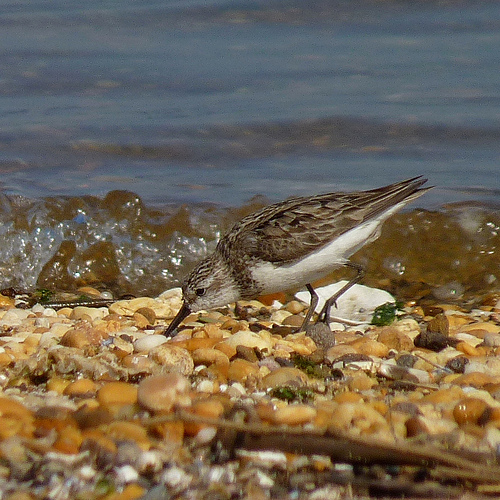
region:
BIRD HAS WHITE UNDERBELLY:
[113, 162, 434, 381]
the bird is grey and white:
[172, 219, 397, 363]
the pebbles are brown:
[145, 330, 430, 422]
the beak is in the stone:
[136, 268, 218, 343]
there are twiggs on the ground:
[182, 391, 449, 476]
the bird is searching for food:
[129, 242, 389, 329]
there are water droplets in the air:
[37, 216, 164, 263]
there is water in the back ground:
[52, 150, 492, 180]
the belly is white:
[258, 240, 394, 294]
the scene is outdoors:
[17, 195, 490, 496]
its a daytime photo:
[9, 191, 499, 452]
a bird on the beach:
[116, 170, 443, 497]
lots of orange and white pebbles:
[92, 302, 372, 497]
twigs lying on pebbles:
[156, 341, 413, 498]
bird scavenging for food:
[108, 145, 456, 396]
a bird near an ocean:
[53, 19, 472, 341]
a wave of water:
[40, 60, 450, 360]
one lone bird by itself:
[95, 90, 493, 402]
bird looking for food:
[99, 161, 495, 403]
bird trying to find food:
[41, 247, 480, 497]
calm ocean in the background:
[72, 0, 404, 222]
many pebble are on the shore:
[144, 304, 279, 438]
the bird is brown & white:
[143, 186, 449, 326]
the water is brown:
[65, 194, 193, 281]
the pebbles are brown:
[153, 339, 268, 414]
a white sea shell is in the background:
[285, 272, 416, 330]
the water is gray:
[180, 51, 368, 136]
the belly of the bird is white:
[205, 193, 437, 298]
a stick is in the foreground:
[173, 359, 455, 494]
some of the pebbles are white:
[55, 317, 200, 356]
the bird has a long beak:
[147, 286, 202, 344]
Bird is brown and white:
[153, 166, 443, 346]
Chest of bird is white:
[246, 231, 386, 298]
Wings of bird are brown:
[207, 168, 424, 265]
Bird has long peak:
[153, 301, 194, 341]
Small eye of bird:
[192, 277, 209, 299]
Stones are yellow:
[0, 287, 499, 497]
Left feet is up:
[318, 257, 377, 327]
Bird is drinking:
[134, 164, 450, 355]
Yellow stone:
[96, 377, 141, 407]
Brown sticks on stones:
[134, 403, 499, 492]